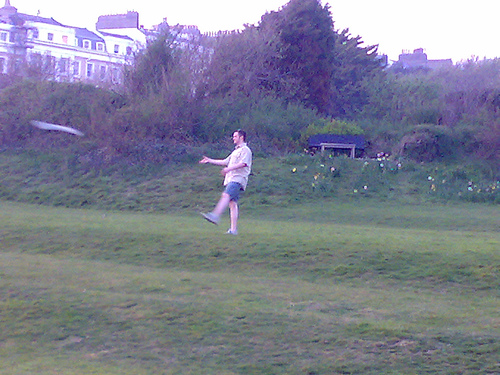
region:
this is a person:
[174, 107, 281, 261]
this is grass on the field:
[97, 195, 159, 267]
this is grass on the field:
[295, 270, 390, 357]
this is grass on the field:
[331, 193, 422, 302]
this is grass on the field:
[91, 238, 178, 328]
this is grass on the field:
[256, 278, 318, 325]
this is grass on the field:
[153, 225, 210, 255]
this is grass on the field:
[267, 223, 418, 314]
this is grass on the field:
[410, 199, 480, 275]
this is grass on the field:
[83, 255, 237, 365]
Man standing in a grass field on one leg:
[193, 124, 263, 241]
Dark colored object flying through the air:
[12, 112, 89, 146]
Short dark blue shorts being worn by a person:
[212, 177, 246, 233]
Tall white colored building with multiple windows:
[24, 11, 81, 88]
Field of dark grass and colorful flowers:
[293, 142, 498, 200]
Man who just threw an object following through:
[12, 112, 266, 245]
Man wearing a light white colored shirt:
[217, 129, 261, 190]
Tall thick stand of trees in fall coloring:
[258, 17, 393, 121]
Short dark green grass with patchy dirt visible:
[75, 314, 458, 369]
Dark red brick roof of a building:
[87, 8, 151, 30]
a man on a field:
[174, 97, 379, 280]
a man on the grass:
[133, 90, 346, 346]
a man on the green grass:
[194, 107, 314, 272]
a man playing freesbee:
[27, 56, 354, 325]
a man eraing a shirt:
[151, 108, 311, 278]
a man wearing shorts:
[147, 95, 344, 326]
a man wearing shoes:
[159, 73, 381, 372]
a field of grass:
[12, 202, 389, 369]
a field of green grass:
[41, 253, 317, 369]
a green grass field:
[107, 196, 337, 338]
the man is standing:
[176, 113, 291, 248]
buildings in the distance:
[10, 2, 262, 116]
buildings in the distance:
[2, 3, 144, 88]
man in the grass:
[197, 124, 269, 254]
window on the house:
[93, 37, 105, 48]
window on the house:
[80, 38, 92, 52]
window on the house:
[63, 36, 71, 48]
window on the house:
[45, 31, 56, 39]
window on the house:
[30, 31, 42, 40]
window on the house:
[69, 57, 77, 77]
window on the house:
[70, 59, 85, 79]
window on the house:
[98, 61, 110, 80]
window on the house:
[108, 65, 119, 88]